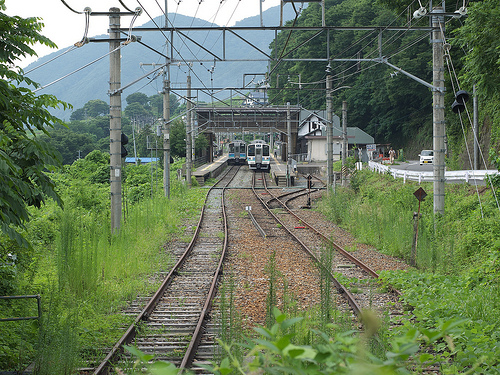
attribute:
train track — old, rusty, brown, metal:
[249, 167, 460, 373]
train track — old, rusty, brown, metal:
[90, 163, 241, 374]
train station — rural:
[189, 102, 375, 189]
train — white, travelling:
[246, 140, 272, 169]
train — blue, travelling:
[225, 139, 249, 166]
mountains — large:
[9, 2, 311, 136]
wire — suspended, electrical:
[159, 1, 183, 64]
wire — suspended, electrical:
[172, 1, 202, 62]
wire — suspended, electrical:
[192, 1, 224, 60]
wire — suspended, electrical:
[200, 1, 241, 61]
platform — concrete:
[269, 151, 294, 178]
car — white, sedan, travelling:
[419, 149, 435, 166]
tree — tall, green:
[1, 0, 74, 295]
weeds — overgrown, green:
[325, 165, 499, 373]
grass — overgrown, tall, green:
[80, 192, 186, 297]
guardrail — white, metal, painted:
[353, 159, 499, 187]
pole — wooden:
[429, 7, 449, 218]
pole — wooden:
[324, 74, 337, 188]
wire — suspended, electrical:
[10, 7, 143, 97]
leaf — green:
[67, 103, 74, 109]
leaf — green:
[25, 76, 32, 86]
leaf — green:
[21, 51, 27, 58]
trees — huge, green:
[267, 1, 434, 146]